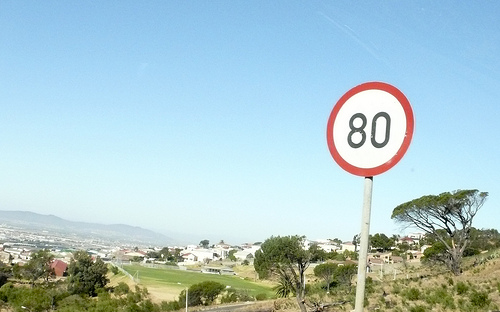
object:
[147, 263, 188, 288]
green grass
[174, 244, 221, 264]
houses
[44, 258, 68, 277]
buildings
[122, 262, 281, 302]
green grass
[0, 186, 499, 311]
field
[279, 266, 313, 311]
trunk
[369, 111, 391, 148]
number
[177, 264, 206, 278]
grass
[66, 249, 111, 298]
trees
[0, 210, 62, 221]
mountain tops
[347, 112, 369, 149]
number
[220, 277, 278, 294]
grass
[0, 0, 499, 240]
sky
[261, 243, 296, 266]
green leaves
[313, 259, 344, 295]
tree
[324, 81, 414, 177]
sign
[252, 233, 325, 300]
small tree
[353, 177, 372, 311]
gray pole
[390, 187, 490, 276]
tree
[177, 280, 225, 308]
tree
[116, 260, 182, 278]
grass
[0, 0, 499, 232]
day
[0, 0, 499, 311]
photo